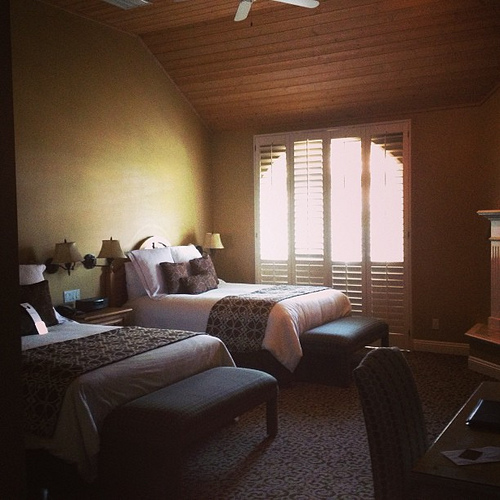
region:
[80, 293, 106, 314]
An alarm clock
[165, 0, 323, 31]
White ceiling fan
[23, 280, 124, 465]
A freshly made bed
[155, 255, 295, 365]
A freshly made bed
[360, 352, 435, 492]
A brown desk chair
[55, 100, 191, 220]
Yellow colored wall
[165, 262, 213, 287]
A set of three brown pillows.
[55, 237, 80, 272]
A hanging wall lamp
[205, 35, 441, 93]
A wooden ceiling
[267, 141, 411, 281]
White blinds with the morning sun coming through.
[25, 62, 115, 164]
this is a wall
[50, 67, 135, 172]
the wall is white in color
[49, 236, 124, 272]
these are lampshades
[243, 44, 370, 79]
this is the ceiling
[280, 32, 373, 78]
the ceiling is made of wood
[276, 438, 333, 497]
this is the floor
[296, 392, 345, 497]
the floor has a carpet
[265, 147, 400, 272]
this is a window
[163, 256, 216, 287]
these are several pillows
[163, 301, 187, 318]
the sheet is white in color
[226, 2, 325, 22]
blades of a ceiling fan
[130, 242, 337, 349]
bed in hotel room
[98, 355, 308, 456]
bench at the end of bed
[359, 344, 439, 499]
chair near desk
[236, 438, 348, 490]
carpet pattern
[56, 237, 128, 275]
dual lamp on wall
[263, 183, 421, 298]
windows with sunlight shinging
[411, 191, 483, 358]
wall of hotel room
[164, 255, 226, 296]
decorative pillows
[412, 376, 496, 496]
desk with objects on top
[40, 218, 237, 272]
three wall mounted lamps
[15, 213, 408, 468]
two matching beds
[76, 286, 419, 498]
two benches at ends of beds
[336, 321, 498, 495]
a chair at a desk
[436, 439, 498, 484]
a paper on a desk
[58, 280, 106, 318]
a white electrical outlet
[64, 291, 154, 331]
an alarm clock on a table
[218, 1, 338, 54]
white celing fan blades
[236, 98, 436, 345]
four door panels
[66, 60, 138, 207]
this is a wall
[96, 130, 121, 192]
the wall is white in color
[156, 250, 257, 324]
this is the bed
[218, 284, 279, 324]
this is a blanket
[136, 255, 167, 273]
this is a pillow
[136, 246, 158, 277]
the pillow is white in color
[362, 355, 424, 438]
this is a chair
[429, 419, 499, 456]
this is a table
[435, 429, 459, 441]
the table is wooden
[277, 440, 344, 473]
this is the floor